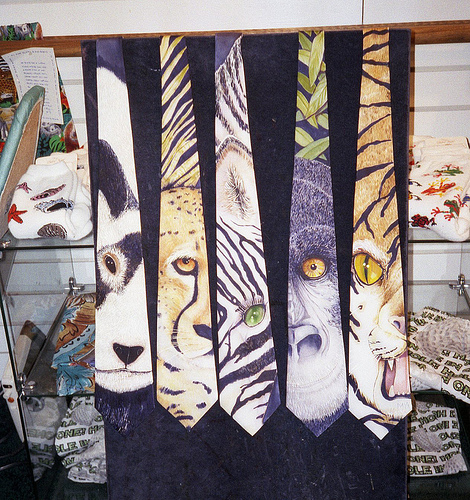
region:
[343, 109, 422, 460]
tie with tiger face on it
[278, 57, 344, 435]
tie with gorilla face on it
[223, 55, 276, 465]
tiwe with zebra face on it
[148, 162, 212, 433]
cheetah face on tie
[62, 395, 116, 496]
green writing on white background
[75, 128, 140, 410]
panda face on a tie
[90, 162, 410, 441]
five ties with faces on them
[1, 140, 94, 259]
blanket with sea shells on it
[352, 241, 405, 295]
yellow eye of a tiger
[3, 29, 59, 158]
paper with writing on it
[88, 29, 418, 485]
animal-print ties on blue fabric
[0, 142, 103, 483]
glass shelves with printed garments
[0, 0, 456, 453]
wooden bar over white wall of raised slats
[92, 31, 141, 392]
black eye on black and white panda tie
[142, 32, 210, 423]
orange eye on tie with black and yellow stripes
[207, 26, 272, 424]
green eye on black and white zebra tie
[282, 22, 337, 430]
orange eye and green leaves on ape tie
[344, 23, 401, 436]
yellow eye and sharp teeth on tiger tie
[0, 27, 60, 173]
piece of paper behind edge of covered board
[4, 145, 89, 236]
seashells and starfish on socks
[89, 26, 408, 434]
Grouping of five ties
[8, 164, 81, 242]
Material with shell images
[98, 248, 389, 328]
five different animal eyes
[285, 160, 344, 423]
Image of gorilla on tie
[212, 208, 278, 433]
Image of zebra on tie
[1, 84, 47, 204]
Ironing board leaning up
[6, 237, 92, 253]
Edge of glass shelf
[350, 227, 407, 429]
Image of tiger on tie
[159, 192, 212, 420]
Image of leopard on tie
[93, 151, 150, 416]
Image of panda on tie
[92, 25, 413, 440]
Five colorful ties hanging on display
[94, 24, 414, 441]
Wild animal-themed ties hanging on black background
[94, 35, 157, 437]
Black and white ties with panda imprint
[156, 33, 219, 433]
Animal print tie featuring cheetah face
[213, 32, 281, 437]
Black and white striped tie with zebra ear and one green eye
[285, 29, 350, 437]
Tie with green leaf pattern and gorilla face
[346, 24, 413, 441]
Tiger print tie with snarling cat face and snake eye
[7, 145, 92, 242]
Folded white blanket printed with seashells and starfish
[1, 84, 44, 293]
Tabletop ironing board with metallic green cover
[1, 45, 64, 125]
Sheet of white paper with printing in middle and border around edge, pinned to wall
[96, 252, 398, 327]
FIVE EYE'S ARE ON INDIVIDUAL TIES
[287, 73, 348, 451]
TIE PROJECTS THE IMAGE OF A GORILLA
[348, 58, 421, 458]
TIE PROJECTS THE IMAGE OF A TIGER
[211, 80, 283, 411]
TIE PROJECTS THE IMAGE OF A ZEBRA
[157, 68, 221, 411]
TIE PROJECTS THE IMAGE OF A LEOPARD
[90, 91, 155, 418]
TIE PROJECTS THE IMAGE OF A PANDA BEAR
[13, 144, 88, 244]
CLOTHING HAS SHELLS PRINTED ON IT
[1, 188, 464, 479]
CLOTHING ITEMS ARE ON A GLASS SHELF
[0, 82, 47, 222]
IRONING BOARD IS LEANING AGAINST SHELVING UNIT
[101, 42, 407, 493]
TIES ARE HANGING ON A BLACK BOARD